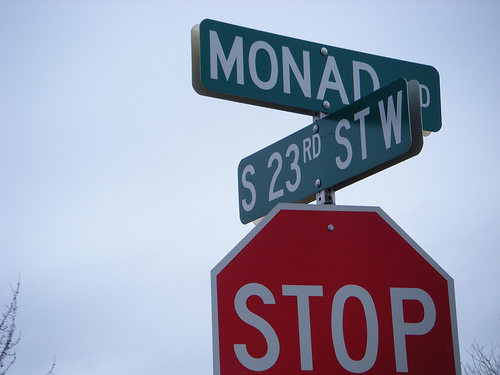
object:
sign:
[236, 78, 412, 226]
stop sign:
[209, 202, 464, 375]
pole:
[312, 110, 335, 206]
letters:
[241, 164, 257, 212]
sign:
[198, 18, 442, 134]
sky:
[0, 0, 500, 375]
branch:
[0, 277, 21, 331]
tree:
[1, 271, 60, 375]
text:
[206, 29, 380, 107]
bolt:
[312, 124, 319, 133]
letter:
[208, 28, 246, 86]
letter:
[248, 39, 279, 91]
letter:
[280, 44, 314, 98]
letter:
[317, 53, 349, 104]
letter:
[333, 118, 354, 170]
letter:
[352, 106, 373, 161]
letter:
[374, 88, 405, 148]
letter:
[352, 60, 381, 104]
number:
[267, 143, 302, 202]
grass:
[462, 337, 499, 374]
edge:
[406, 78, 424, 154]